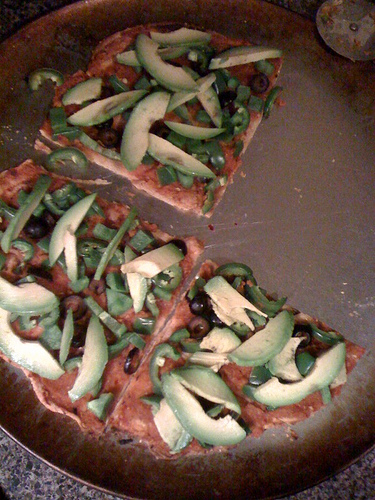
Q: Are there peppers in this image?
A: Yes, there is a pepper.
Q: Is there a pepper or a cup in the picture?
A: Yes, there is a pepper.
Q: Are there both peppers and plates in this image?
A: No, there is a pepper but no plates.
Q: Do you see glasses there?
A: No, there are no glasses.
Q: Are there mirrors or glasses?
A: No, there are no glasses or mirrors.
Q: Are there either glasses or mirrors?
A: No, there are no glasses or mirrors.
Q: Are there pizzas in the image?
A: Yes, there is a pizza.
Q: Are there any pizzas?
A: Yes, there is a pizza.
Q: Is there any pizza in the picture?
A: Yes, there is a pizza.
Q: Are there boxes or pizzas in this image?
A: Yes, there is a pizza.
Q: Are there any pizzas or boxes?
A: Yes, there is a pizza.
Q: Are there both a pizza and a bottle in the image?
A: No, there is a pizza but no bottles.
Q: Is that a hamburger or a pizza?
A: That is a pizza.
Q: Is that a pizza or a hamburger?
A: That is a pizza.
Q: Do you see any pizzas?
A: Yes, there is a pizza.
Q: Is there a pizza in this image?
A: Yes, there is a pizza.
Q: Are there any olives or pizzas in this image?
A: Yes, there is a pizza.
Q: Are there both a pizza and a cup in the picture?
A: No, there is a pizza but no cups.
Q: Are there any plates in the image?
A: No, there are no plates.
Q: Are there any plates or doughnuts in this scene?
A: No, there are no plates or doughnuts.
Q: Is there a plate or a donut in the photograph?
A: No, there are no plates or donuts.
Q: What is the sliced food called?
A: The food is a pizza.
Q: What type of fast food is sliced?
A: The fast food is a pizza.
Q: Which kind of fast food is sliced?
A: The fast food is a pizza.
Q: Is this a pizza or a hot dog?
A: This is a pizza.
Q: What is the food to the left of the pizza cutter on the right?
A: The food is a pizza.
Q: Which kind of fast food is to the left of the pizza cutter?
A: The food is a pizza.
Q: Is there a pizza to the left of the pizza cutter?
A: Yes, there is a pizza to the left of the pizza cutter.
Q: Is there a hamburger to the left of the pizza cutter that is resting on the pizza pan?
A: No, there is a pizza to the left of the pizza cutter.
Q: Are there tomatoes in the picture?
A: No, there are no tomatoes.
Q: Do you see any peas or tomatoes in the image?
A: No, there are no tomatoes or peas.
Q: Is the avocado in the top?
A: Yes, the avocado is in the top of the image.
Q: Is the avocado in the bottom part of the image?
A: No, the avocado is in the top of the image.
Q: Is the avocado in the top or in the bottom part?
A: The avocado is in the top of the image.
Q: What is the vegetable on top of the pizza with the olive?
A: The vegetable is an avocado.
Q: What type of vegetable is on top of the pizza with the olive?
A: The vegetable is an avocado.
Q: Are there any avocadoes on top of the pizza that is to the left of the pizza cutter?
A: Yes, there is an avocado on top of the pizza.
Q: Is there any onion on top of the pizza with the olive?
A: No, there is an avocado on top of the pizza.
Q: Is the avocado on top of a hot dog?
A: No, the avocado is on top of a pizza.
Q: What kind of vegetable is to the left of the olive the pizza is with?
A: The vegetable is an avocado.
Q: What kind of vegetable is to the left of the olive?
A: The vegetable is an avocado.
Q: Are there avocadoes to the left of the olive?
A: Yes, there is an avocado to the left of the olive.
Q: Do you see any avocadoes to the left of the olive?
A: Yes, there is an avocado to the left of the olive.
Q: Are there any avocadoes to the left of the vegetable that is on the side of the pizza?
A: Yes, there is an avocado to the left of the olive.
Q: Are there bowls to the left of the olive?
A: No, there is an avocado to the left of the olive.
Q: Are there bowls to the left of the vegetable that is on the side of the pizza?
A: No, there is an avocado to the left of the olive.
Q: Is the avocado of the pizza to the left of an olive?
A: Yes, the avocado is to the left of an olive.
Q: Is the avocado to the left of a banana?
A: No, the avocado is to the left of an olive.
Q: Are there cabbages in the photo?
A: No, there are no cabbages.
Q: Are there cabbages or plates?
A: No, there are no cabbages or plates.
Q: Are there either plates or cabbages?
A: No, there are no cabbages or plates.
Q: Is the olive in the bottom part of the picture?
A: No, the olive is in the top of the image.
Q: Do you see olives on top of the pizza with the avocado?
A: Yes, there is an olive on top of the pizza.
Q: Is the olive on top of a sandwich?
A: No, the olive is on top of the pizza.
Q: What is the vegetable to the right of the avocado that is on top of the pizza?
A: The vegetable is an olive.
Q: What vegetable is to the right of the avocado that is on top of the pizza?
A: The vegetable is an olive.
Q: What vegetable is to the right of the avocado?
A: The vegetable is an olive.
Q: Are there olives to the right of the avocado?
A: Yes, there is an olive to the right of the avocado.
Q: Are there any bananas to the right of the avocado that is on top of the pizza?
A: No, there is an olive to the right of the avocado.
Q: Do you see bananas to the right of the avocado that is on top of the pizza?
A: No, there is an olive to the right of the avocado.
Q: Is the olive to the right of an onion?
A: No, the olive is to the right of the avocado.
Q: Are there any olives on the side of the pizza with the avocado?
A: Yes, there is an olive on the side of the pizza.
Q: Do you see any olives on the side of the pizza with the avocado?
A: Yes, there is an olive on the side of the pizza.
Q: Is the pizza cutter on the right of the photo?
A: Yes, the pizza cutter is on the right of the image.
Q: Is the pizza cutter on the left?
A: No, the pizza cutter is on the right of the image.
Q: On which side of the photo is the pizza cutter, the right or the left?
A: The pizza cutter is on the right of the image.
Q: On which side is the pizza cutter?
A: The pizza cutter is on the right of the image.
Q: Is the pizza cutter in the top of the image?
A: Yes, the pizza cutter is in the top of the image.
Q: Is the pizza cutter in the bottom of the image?
A: No, the pizza cutter is in the top of the image.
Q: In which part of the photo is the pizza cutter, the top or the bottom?
A: The pizza cutter is in the top of the image.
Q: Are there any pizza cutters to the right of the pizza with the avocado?
A: Yes, there is a pizza cutter to the right of the pizza.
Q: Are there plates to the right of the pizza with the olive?
A: No, there is a pizza cutter to the right of the pizza.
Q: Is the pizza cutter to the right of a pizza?
A: Yes, the pizza cutter is to the right of a pizza.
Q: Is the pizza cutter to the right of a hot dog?
A: No, the pizza cutter is to the right of a pizza.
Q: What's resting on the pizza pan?
A: The pizza cutter is resting on the pizza pan.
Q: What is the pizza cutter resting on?
A: The pizza cutter is resting on the pizza pan.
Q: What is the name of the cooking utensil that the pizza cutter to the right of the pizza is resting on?
A: The cooking utensil is a pizza pan.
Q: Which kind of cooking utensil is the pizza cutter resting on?
A: The pizza cutter is resting on the pizza pan.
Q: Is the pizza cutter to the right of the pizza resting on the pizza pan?
A: Yes, the pizza cutter is resting on the pizza pan.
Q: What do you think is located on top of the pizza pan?
A: The pizza cutter is on top of the pizza pan.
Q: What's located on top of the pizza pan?
A: The pizza cutter is on top of the pizza pan.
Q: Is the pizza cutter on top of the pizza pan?
A: Yes, the pizza cutter is on top of the pizza pan.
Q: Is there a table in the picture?
A: Yes, there is a table.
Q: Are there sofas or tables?
A: Yes, there is a table.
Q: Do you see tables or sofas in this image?
A: Yes, there is a table.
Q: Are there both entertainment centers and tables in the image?
A: No, there is a table but no entertainment centers.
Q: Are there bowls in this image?
A: No, there are no bowls.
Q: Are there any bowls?
A: No, there are no bowls.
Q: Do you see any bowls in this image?
A: No, there are no bowls.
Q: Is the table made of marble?
A: Yes, the table is made of marble.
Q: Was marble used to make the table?
A: Yes, the table is made of marble.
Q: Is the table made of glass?
A: No, the table is made of marble.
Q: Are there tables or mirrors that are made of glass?
A: No, there is a table but it is made of marble.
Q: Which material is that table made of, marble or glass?
A: The table is made of marble.